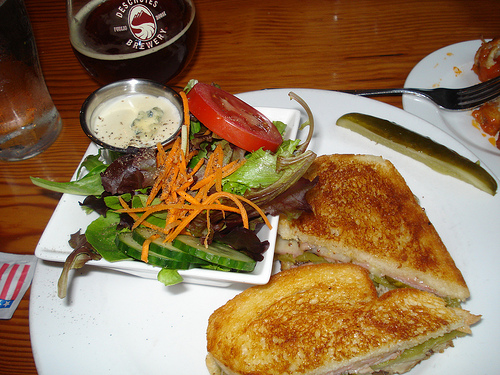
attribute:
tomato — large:
[164, 71, 294, 171]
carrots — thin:
[119, 148, 221, 227]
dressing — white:
[104, 96, 166, 150]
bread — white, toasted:
[289, 314, 363, 344]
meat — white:
[365, 351, 416, 372]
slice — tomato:
[195, 76, 303, 156]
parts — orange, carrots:
[154, 156, 232, 218]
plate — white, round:
[28, 87, 498, 369]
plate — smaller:
[390, 34, 499, 174]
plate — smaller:
[374, 24, 499, 183]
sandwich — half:
[194, 256, 474, 372]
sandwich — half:
[245, 150, 476, 324]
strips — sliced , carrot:
[133, 147, 271, 237]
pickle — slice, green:
[335, 105, 498, 204]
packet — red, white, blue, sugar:
[2, 245, 52, 322]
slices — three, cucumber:
[106, 221, 261, 271]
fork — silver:
[349, 71, 495, 108]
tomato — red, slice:
[174, 75, 289, 151]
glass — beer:
[64, 2, 227, 88]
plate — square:
[31, 85, 321, 285]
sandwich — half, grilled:
[202, 269, 483, 372]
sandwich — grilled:
[194, 143, 469, 373]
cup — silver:
[74, 77, 190, 154]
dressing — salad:
[103, 89, 170, 140]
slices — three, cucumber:
[124, 226, 258, 279]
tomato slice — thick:
[179, 76, 284, 155]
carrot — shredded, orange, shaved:
[118, 87, 272, 261]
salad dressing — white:
[93, 90, 181, 145]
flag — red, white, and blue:
[0, 257, 32, 311]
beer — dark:
[74, 5, 199, 89]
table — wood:
[0, 2, 500, 371]